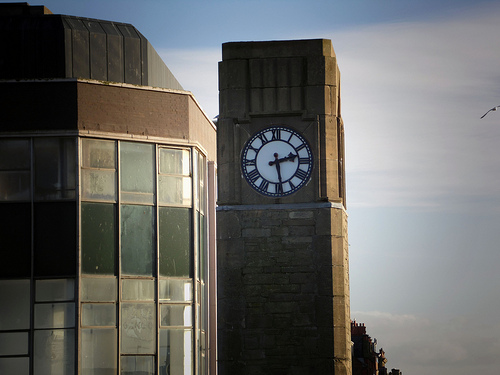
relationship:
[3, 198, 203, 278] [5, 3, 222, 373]
windows on a building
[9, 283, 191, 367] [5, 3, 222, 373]
windows on a building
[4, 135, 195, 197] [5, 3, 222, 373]
windows on a building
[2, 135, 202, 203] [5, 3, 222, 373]
windows on a building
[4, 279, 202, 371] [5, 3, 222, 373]
windows on a building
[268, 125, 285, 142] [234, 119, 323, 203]
numeral on clock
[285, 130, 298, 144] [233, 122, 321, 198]
numeral on clock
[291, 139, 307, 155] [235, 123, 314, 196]
numeral on clock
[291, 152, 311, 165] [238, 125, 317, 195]
numeral on clock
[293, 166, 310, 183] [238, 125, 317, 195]
numeral on clock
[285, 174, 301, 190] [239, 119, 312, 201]
numeral on clock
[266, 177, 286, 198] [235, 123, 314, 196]
numeral on clock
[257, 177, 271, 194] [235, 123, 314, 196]
numeral on clock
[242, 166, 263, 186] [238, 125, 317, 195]
numeral on clock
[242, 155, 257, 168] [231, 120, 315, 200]
numeral on clock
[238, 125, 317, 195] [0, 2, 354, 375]
clock on building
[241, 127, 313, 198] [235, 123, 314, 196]
clock on clock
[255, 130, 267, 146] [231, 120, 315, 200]
numerals on clock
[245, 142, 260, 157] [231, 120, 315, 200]
numerals on clock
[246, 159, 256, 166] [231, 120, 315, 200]
numeral on clock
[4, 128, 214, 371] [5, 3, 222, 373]
wall on building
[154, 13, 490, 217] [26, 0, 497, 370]
clouds in sky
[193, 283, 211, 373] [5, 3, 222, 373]
windows on building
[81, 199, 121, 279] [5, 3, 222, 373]
windows on building